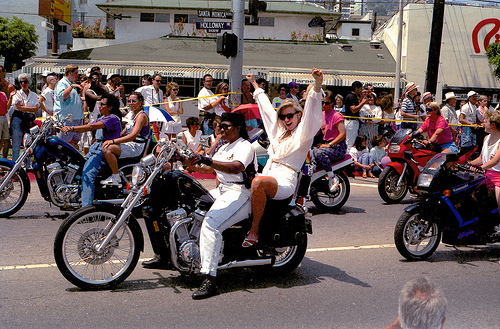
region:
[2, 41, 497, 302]
female bikers in a parade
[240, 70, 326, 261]
a lady riding on the back of a motorcycle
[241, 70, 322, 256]
the lady has both arms up in the air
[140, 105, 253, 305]
the driver of the motorcycle has her feet on the ground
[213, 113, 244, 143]
the lady is wearing sunglasses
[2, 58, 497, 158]
people are watching from the roadside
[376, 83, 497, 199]
a red motorcycle is near the crowd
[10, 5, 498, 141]
shops line the road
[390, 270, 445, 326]
a man with gray hair is watching the parade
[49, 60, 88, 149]
a man with his arm up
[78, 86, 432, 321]
Motorcycle parade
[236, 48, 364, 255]
White outfit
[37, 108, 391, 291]
Motorcycles on the roadway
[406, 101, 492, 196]
Lady on a motorcycle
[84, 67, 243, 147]
People watching the motorcycle riders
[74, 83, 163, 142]
Two people on bike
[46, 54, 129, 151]
Man with a blue shirt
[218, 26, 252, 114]
Light pole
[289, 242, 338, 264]
White paint on the road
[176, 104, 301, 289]
Black person on the motorcycle riding down the road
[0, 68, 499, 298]
People sitting on motorcycles.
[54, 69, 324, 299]
Two women riding a motorcycle.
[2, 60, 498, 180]
Spectators watching a motorcycle parade.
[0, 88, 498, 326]
Men and women riding motorcycles on the street.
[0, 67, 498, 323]
Motorcycle riders in the street.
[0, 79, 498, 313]
Women riding motorcycles.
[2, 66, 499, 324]
Motorcycle show with women riding motorcycles.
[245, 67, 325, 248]
Woman wearing a white blouse with arms raised in the air.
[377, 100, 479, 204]
Woman riding a red motorcycle.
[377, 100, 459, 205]
Woman riding a red motorcycle in a parade.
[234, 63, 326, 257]
woman has hands up on motorcylce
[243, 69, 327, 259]
The woman with her arms in the air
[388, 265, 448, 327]
The head of the man mostly off screen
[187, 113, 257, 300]
The man ahead of the woman with her hands up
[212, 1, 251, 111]
The street light pole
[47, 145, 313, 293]
The motorcycle the people in white are on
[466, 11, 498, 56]
The red writing on the wall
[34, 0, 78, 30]
The yellow sign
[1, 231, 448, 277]
The white line down the road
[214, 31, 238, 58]
The cross walk signal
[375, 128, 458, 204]
The red motorcycle